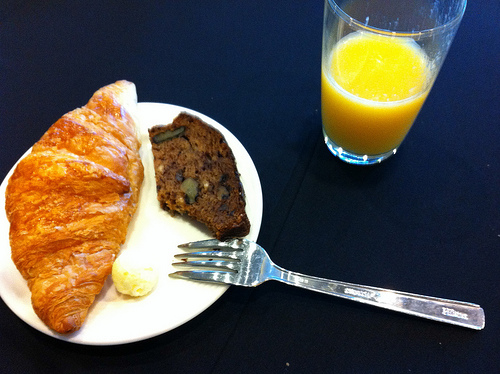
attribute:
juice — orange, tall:
[316, 27, 423, 152]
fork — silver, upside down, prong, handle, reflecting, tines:
[182, 236, 476, 334]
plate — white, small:
[132, 98, 167, 111]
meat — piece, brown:
[163, 121, 236, 218]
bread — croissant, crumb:
[42, 94, 118, 280]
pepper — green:
[149, 129, 189, 141]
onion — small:
[174, 181, 211, 199]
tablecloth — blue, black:
[166, 35, 246, 66]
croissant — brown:
[98, 71, 142, 138]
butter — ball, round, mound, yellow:
[118, 238, 158, 308]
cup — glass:
[313, 8, 391, 74]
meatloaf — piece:
[181, 195, 241, 232]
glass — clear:
[327, 134, 426, 168]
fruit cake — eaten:
[221, 216, 245, 226]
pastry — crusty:
[16, 177, 53, 203]